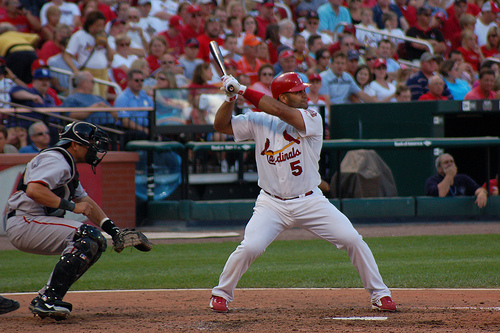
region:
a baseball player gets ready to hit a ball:
[201, 31, 403, 321]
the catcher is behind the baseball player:
[6, 122, 151, 317]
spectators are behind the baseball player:
[2, 1, 488, 158]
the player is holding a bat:
[206, 39, 318, 144]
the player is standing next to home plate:
[321, 311, 394, 331]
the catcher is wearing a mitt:
[106, 221, 151, 256]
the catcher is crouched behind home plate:
[321, 311, 391, 328]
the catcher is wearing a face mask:
[85, 128, 113, 170]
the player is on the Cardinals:
[203, 35, 405, 320]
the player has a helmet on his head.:
[262, 70, 310, 95]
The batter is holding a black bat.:
[206, 37, 233, 95]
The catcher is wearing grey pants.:
[4, 211, 114, 319]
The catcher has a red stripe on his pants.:
[18, 215, 80, 257]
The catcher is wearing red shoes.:
[206, 292, 396, 314]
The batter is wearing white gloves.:
[219, 70, 247, 110]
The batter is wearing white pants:
[211, 187, 394, 312]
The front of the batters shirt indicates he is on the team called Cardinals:
[258, 130, 307, 189]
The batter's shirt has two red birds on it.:
[258, 126, 302, 158]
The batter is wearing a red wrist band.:
[241, 84, 266, 114]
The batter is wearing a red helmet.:
[271, 68, 311, 99]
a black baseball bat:
[199, 32, 238, 101]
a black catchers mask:
[69, 115, 114, 180]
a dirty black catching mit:
[107, 213, 167, 252]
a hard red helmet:
[263, 56, 315, 117]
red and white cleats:
[202, 291, 418, 331]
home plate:
[316, 298, 399, 328]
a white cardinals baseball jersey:
[191, 49, 405, 324]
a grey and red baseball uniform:
[7, 97, 128, 319]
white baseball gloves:
[211, 71, 268, 114]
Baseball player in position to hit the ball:
[172, 26, 434, 321]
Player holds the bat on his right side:
[188, 31, 415, 326]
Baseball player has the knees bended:
[177, 29, 419, 317]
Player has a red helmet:
[188, 29, 415, 324]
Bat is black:
[190, 27, 255, 108]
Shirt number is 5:
[228, 108, 337, 204]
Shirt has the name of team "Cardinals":
[227, 105, 335, 200]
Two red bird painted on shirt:
[256, 124, 305, 151]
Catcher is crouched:
[1, 106, 173, 330]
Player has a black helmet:
[1, 104, 158, 321]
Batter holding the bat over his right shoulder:
[187, 21, 408, 322]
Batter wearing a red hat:
[197, 61, 405, 321]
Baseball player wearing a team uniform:
[192, 58, 420, 320]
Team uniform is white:
[201, 62, 409, 319]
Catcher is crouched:
[7, 104, 157, 325]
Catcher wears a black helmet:
[1, 108, 153, 323]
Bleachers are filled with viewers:
[27, 10, 498, 110]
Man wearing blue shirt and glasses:
[114, 64, 162, 136]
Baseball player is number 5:
[195, 57, 409, 318]